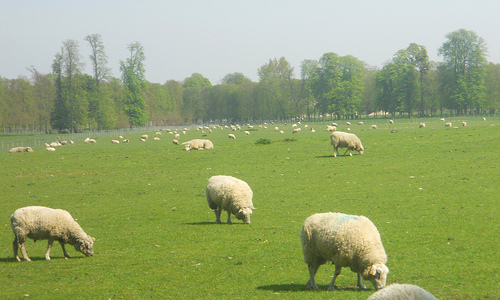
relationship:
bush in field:
[250, 133, 274, 149] [374, 155, 492, 232]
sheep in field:
[298, 206, 388, 293] [0, 111, 497, 298]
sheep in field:
[206, 175, 257, 225] [0, 111, 497, 298]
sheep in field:
[8, 203, 98, 264] [0, 111, 497, 298]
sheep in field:
[326, 126, 367, 154] [0, 111, 497, 298]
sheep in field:
[177, 133, 217, 153] [0, 111, 497, 298]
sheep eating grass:
[300, 211, 389, 291] [375, 125, 483, 269]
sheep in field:
[298, 206, 388, 293] [4, 133, 497, 298]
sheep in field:
[331, 131, 365, 157] [4, 133, 497, 298]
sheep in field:
[199, 167, 257, 225] [4, 133, 497, 298]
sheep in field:
[8, 203, 98, 264] [4, 133, 497, 298]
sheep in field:
[183, 139, 214, 151] [4, 133, 497, 298]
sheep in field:
[206, 175, 257, 225] [66, 110, 496, 221]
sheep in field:
[298, 206, 388, 293] [402, 136, 493, 266]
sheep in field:
[206, 175, 257, 225] [402, 136, 493, 266]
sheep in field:
[331, 131, 365, 157] [402, 136, 493, 266]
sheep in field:
[108, 136, 123, 145] [402, 136, 493, 266]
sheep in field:
[8, 203, 98, 264] [402, 136, 493, 266]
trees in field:
[431, 24, 493, 117] [105, 82, 474, 185]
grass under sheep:
[360, 158, 475, 253] [201, 171, 253, 225]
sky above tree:
[39, 11, 499, 64] [86, 30, 121, 139]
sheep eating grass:
[9, 205, 95, 261] [67, 246, 137, 284]